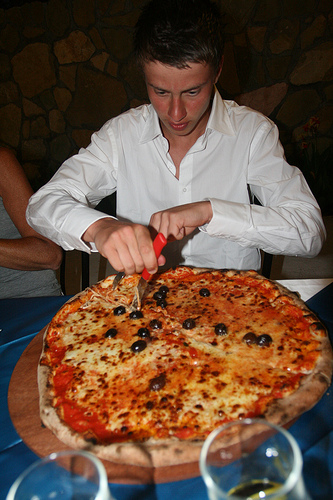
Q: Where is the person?
A: Next to pizza.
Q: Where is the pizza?
A: On the table.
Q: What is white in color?
A: The shirt.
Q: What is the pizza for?
A: Eating.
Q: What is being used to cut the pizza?
A: A red object.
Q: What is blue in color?
A: Table cloth.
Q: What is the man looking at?
A: The pizza.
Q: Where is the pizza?
A: On the wooden board.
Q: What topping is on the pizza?
A: Black olives.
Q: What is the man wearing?
A: A white button-down shirt.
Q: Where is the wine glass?
A: On the table.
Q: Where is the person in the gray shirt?
A: Next to the man cutting the pizza.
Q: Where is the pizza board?
A: On the table.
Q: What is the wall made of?
A: Stone.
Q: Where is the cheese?
A: On the pizza.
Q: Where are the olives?
A: On the pizza.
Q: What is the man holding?
A: Knife.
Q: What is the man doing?
A: Cutting food.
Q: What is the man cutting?
A: Pizza.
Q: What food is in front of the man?
A: Pizza.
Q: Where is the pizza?
A: On the table.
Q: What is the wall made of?
A: Stone.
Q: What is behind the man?
A: Wall.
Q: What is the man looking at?
A: Pizza.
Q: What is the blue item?
A: Table cloth.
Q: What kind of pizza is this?
A: Olive and cheese pizza.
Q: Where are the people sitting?
A: In chairs behind table.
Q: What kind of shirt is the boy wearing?
A: Long sleeved and collared.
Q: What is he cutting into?
A: Pizza.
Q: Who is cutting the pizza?
A: The boy.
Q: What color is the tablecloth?
A: Blue.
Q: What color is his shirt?
A: White.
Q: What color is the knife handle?
A: Orange.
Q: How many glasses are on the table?
A: 2.